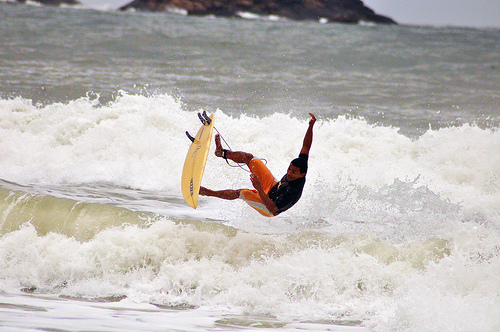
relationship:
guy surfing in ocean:
[198, 113, 317, 218] [2, 0, 499, 330]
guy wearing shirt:
[198, 113, 317, 218] [270, 154, 309, 216]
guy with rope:
[198, 113, 317, 218] [205, 121, 267, 174]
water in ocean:
[209, 26, 448, 114] [28, 17, 154, 89]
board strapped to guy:
[181, 112, 215, 208] [198, 113, 317, 218]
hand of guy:
[300, 113, 319, 128] [198, 113, 317, 218]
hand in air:
[300, 113, 319, 128] [0, 1, 498, 225]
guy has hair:
[198, 113, 317, 218] [172, 110, 214, 211]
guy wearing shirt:
[198, 113, 317, 218] [274, 184, 310, 210]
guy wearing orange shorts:
[198, 113, 317, 218] [237, 155, 277, 217]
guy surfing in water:
[198, 113, 317, 218] [0, 4, 495, 330]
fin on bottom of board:
[198, 107, 211, 124] [180, 112, 215, 209]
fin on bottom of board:
[183, 129, 196, 144] [180, 112, 215, 209]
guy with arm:
[198, 113, 317, 218] [300, 111, 317, 169]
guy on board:
[198, 113, 317, 218] [182, 109, 216, 211]